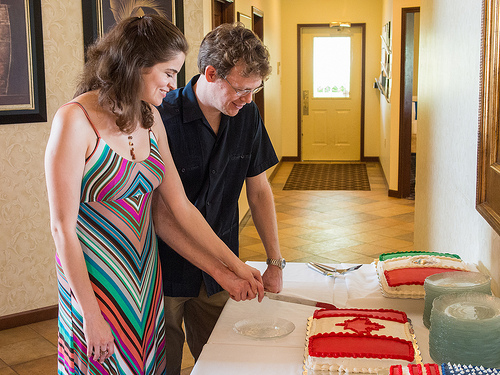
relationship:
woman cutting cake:
[42, 4, 263, 375] [302, 303, 424, 375]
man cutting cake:
[162, 23, 282, 373] [302, 303, 424, 375]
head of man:
[197, 22, 273, 117] [127, 17, 287, 315]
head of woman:
[194, 21, 274, 116] [42, 4, 263, 375]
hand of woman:
[80, 316, 115, 363] [42, 4, 263, 375]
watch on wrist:
[106, 229, 356, 263] [260, 253, 286, 273]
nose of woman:
[168, 71, 181, 88] [42, 4, 263, 375]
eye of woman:
[164, 72, 173, 79] [42, 4, 263, 375]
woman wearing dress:
[42, 4, 263, 375] [52, 100, 167, 372]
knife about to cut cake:
[261, 287, 339, 314] [296, 301, 421, 374]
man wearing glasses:
[152, 23, 286, 375] [231, 77, 268, 97]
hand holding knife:
[215, 270, 255, 302] [251, 289, 338, 311]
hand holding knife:
[234, 261, 264, 293] [251, 289, 338, 311]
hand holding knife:
[259, 256, 285, 296] [251, 289, 338, 311]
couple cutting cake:
[34, 4, 282, 373] [295, 290, 440, 373]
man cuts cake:
[152, 23, 286, 375] [299, 304, 423, 370]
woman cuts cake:
[42, 4, 263, 375] [299, 304, 423, 370]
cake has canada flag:
[302, 304, 442, 374] [313, 306, 418, 361]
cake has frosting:
[302, 304, 442, 374] [373, 248, 467, 296]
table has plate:
[188, 249, 495, 373] [234, 312, 300, 345]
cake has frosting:
[356, 246, 488, 301] [378, 251, 475, 296]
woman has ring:
[57, 25, 230, 373] [95, 341, 112, 356]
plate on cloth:
[232, 316, 295, 340] [188, 258, 498, 373]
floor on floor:
[0, 191, 500, 374] [1, 161, 413, 372]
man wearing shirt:
[162, 23, 282, 373] [167, 79, 275, 270]